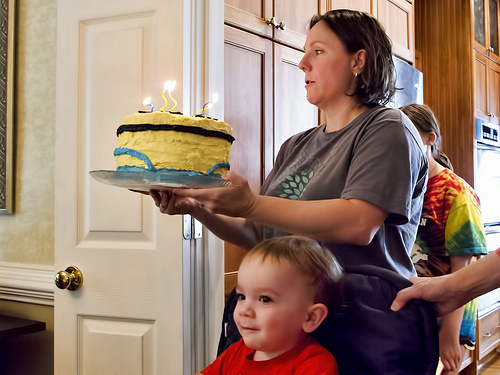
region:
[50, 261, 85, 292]
gold door knob on beige door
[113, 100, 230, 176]
yellow, brown and aqua colored icing on cake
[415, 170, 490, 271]
girl's multi-colored tee shirt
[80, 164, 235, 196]
clear glass platter holding cake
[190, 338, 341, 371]
little boy's red tee shirt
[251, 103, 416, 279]
lady wearing gray tee shirt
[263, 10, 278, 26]
door knob on right upper cabinet door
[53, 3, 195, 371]
beige opened door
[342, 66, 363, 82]
earring in left ear of woman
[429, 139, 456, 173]
ponytail of young girl behind the mother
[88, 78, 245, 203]
Yellow birthday cake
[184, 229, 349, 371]
Boy in red shirt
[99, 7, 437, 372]
Woman holding cake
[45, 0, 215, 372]
Open white door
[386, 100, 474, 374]
Girl in a tie dye shirt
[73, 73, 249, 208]
Birthday cake with lit candels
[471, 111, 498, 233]
Oven in the between cabinets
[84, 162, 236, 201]
Glass plate with birthday cake on top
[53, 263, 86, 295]
Doorknob on white door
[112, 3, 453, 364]
Woman with brown hair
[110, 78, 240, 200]
The cake is yellow.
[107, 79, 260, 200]
The cake is a minion.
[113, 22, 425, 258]
The woman is holding a cake.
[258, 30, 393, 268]
The is wearing a grey shirt.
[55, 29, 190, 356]
The door is white.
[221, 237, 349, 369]
The boy is sitting.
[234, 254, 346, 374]
The boy is young.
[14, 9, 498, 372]
They are in their home.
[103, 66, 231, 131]
The candles are lit.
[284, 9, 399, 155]
She has brown hair.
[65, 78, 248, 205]
birthday cake with candles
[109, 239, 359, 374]
kid wearing red shirt sitting in chair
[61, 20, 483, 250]
woman holding a cake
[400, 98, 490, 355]
girl in a tie-dye shirt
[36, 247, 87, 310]
gold knob on a door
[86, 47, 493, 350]
people celebrating a birthday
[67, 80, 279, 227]
Minion cake with candles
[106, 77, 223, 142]
Candles on top of a cake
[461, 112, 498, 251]
Kitchen oven in the kitchen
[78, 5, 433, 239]
lady carrying kids cake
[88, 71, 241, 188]
a yellow birthday cake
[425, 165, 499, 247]
a person wearing a tie dye shirt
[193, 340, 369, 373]
baby is wearing an orange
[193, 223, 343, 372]
a baby is having a birthday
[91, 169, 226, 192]
a white glass pan under cake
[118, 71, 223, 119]
candles on a birthday cake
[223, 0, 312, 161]
a brown cupboard with handles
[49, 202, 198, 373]
a white door that is open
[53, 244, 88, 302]
a copper door knob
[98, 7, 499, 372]
many people celebrating a birthday